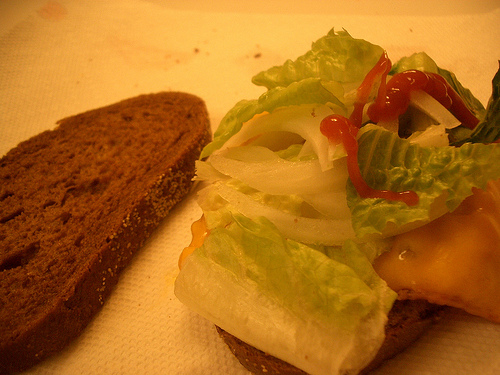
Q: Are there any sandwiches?
A: Yes, there is a sandwich.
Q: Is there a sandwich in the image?
A: Yes, there is a sandwich.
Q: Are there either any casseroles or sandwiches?
A: Yes, there is a sandwich.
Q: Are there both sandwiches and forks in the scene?
A: No, there is a sandwich but no forks.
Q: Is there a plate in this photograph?
A: No, there are no plates.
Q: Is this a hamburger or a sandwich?
A: This is a sandwich.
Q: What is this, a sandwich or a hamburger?
A: This is a sandwich.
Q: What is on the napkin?
A: The sandwich is on the napkin.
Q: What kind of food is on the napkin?
A: The food is a sandwich.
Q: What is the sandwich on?
A: The sandwich is on the napkin.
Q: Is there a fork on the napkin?
A: No, there is a sandwich on the napkin.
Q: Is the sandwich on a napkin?
A: Yes, the sandwich is on a napkin.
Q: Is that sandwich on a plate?
A: No, the sandwich is on a napkin.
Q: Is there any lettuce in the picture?
A: Yes, there is lettuce.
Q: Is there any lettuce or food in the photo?
A: Yes, there is lettuce.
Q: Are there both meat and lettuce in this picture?
A: No, there is lettuce but no meat.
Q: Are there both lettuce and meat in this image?
A: No, there is lettuce but no meat.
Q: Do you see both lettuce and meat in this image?
A: No, there is lettuce but no meat.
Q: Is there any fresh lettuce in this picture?
A: Yes, there is fresh lettuce.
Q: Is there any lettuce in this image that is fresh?
A: Yes, there is lettuce that is fresh.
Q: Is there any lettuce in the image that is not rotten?
A: Yes, there is fresh lettuce.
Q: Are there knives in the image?
A: No, there are no knives.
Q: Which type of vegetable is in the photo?
A: The vegetable is lettuce.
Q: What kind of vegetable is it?
A: The vegetable is lettuce.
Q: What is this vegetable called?
A: That is lettuce.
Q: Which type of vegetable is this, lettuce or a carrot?
A: That is lettuce.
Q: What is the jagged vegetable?
A: The vegetable is lettuce.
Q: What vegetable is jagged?
A: The vegetable is lettuce.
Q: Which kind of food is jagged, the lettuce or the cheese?
A: The lettuce is jagged.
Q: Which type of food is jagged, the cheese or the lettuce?
A: The lettuce is jagged.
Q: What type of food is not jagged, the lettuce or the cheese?
A: The cheese is not jagged.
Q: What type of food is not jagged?
A: The food is cheese.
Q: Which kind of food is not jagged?
A: The food is cheese.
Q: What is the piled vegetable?
A: The vegetable is lettuce.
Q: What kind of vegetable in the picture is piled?
A: The vegetable is lettuce.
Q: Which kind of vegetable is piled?
A: The vegetable is lettuce.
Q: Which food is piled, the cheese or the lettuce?
A: The lettuce is piled.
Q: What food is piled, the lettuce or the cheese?
A: The lettuce is piled.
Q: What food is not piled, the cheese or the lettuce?
A: The cheese is not piled.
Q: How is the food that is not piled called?
A: The food is cheese.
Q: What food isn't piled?
A: The food is cheese.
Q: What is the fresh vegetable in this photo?
A: The vegetable is lettuce.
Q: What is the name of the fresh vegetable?
A: The vegetable is lettuce.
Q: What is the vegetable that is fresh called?
A: The vegetable is lettuce.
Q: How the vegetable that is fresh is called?
A: The vegetable is lettuce.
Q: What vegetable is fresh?
A: The vegetable is lettuce.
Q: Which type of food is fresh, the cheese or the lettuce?
A: The lettuce is fresh.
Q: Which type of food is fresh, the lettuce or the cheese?
A: The lettuce is fresh.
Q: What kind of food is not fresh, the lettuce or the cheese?
A: The cheese is not fresh.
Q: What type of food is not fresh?
A: The food is cheese.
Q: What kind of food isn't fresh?
A: The food is cheese.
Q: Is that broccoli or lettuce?
A: That is lettuce.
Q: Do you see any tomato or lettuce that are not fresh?
A: No, there is lettuce but it is fresh.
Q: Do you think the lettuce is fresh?
A: Yes, the lettuce is fresh.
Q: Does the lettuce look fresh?
A: Yes, the lettuce is fresh.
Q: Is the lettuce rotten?
A: No, the lettuce is fresh.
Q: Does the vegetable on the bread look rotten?
A: No, the lettuce is fresh.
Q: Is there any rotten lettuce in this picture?
A: No, there is lettuce but it is fresh.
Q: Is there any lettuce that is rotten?
A: No, there is lettuce but it is fresh.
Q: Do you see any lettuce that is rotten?
A: No, there is lettuce but it is fresh.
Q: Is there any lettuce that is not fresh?
A: No, there is lettuce but it is fresh.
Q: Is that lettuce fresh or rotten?
A: The lettuce is fresh.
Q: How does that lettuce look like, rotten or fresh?
A: The lettuce is fresh.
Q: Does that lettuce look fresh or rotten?
A: The lettuce is fresh.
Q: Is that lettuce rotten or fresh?
A: The lettuce is fresh.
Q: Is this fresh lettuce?
A: Yes, this is fresh lettuce.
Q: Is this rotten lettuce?
A: No, this is fresh lettuce.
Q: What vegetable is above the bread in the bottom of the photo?
A: The vegetable is lettuce.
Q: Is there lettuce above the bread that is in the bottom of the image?
A: Yes, there is lettuce above the bread.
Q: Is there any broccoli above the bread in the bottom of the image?
A: No, there is lettuce above the bread.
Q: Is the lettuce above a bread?
A: Yes, the lettuce is above a bread.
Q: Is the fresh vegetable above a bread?
A: Yes, the lettuce is above a bread.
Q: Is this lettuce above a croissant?
A: No, the lettuce is above a bread.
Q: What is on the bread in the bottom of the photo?
A: The lettuce is on the bread.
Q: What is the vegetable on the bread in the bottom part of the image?
A: The vegetable is lettuce.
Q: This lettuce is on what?
A: The lettuce is on the bread.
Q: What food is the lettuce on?
A: The lettuce is on the bread.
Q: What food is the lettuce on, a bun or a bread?
A: The lettuce is on a bread.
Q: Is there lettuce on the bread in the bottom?
A: Yes, there is lettuce on the bread.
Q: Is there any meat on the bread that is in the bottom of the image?
A: No, there is lettuce on the bread.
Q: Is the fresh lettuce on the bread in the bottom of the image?
A: Yes, the lettuce is on the bread.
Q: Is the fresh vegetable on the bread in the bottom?
A: Yes, the lettuce is on the bread.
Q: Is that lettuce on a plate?
A: No, the lettuce is on the bread.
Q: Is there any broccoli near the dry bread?
A: No, there is lettuce near the bread.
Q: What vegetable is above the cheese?
A: The vegetable is lettuce.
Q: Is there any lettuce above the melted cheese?
A: Yes, there is lettuce above the cheese.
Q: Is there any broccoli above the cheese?
A: No, there is lettuce above the cheese.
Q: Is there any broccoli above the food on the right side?
A: No, there is lettuce above the cheese.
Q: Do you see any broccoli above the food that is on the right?
A: No, there is lettuce above the cheese.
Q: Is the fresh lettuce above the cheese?
A: Yes, the lettuce is above the cheese.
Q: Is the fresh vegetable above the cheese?
A: Yes, the lettuce is above the cheese.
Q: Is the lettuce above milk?
A: No, the lettuce is above the cheese.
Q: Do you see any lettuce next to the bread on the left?
A: Yes, there is lettuce next to the bread.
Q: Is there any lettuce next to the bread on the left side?
A: Yes, there is lettuce next to the bread.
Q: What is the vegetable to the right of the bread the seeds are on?
A: The vegetable is lettuce.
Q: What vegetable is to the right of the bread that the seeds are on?
A: The vegetable is lettuce.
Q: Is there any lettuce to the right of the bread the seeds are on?
A: Yes, there is lettuce to the right of the bread.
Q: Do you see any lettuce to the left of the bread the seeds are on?
A: No, the lettuce is to the right of the bread.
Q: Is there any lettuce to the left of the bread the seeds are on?
A: No, the lettuce is to the right of the bread.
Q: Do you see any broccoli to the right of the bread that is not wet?
A: No, there is lettuce to the right of the bread.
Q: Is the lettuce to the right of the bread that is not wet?
A: Yes, the lettuce is to the right of the bread.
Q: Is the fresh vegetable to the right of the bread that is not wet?
A: Yes, the lettuce is to the right of the bread.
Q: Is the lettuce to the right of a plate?
A: No, the lettuce is to the right of the bread.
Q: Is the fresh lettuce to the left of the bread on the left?
A: No, the lettuce is to the right of the bread.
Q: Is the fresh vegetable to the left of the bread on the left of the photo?
A: No, the lettuce is to the right of the bread.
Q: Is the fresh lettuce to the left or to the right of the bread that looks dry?
A: The lettuce is to the right of the bread.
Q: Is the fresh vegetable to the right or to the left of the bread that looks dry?
A: The lettuce is to the right of the bread.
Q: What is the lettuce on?
A: The lettuce is on the bread.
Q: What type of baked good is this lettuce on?
A: The lettuce is on the bread.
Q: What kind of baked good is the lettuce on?
A: The lettuce is on the bread.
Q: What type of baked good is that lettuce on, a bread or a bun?
A: The lettuce is on a bread.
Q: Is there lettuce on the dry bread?
A: Yes, there is lettuce on the bread.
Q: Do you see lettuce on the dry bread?
A: Yes, there is lettuce on the bread.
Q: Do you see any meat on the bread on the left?
A: No, there is lettuce on the bread.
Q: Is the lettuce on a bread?
A: Yes, the lettuce is on a bread.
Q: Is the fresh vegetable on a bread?
A: Yes, the lettuce is on a bread.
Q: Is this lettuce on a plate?
A: No, the lettuce is on a bread.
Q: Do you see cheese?
A: Yes, there is cheese.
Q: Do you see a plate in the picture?
A: No, there are no plates.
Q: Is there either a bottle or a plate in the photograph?
A: No, there are no plates or bottles.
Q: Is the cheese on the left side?
A: No, the cheese is on the right of the image.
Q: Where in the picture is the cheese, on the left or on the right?
A: The cheese is on the right of the image.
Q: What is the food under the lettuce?
A: The food is cheese.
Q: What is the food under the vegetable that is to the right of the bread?
A: The food is cheese.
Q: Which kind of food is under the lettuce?
A: The food is cheese.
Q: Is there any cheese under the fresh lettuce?
A: Yes, there is cheese under the lettuce.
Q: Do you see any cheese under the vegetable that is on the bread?
A: Yes, there is cheese under the lettuce.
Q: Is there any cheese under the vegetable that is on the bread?
A: Yes, there is cheese under the lettuce.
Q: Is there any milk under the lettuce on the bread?
A: No, there is cheese under the lettuce.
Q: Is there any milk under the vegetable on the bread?
A: No, there is cheese under the lettuce.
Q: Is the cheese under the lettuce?
A: Yes, the cheese is under the lettuce.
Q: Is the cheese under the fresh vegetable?
A: Yes, the cheese is under the lettuce.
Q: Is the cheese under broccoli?
A: No, the cheese is under the lettuce.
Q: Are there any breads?
A: Yes, there is a bread.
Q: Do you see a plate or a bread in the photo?
A: Yes, there is a bread.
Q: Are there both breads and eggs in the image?
A: No, there is a bread but no eggs.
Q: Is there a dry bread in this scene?
A: Yes, there is a dry bread.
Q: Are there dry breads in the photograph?
A: Yes, there is a dry bread.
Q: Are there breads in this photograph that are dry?
A: Yes, there is a bread that is dry.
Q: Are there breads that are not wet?
A: Yes, there is a dry bread.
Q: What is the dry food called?
A: The food is a bread.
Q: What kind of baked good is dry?
A: The baked good is a bread.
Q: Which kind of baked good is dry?
A: The baked good is a bread.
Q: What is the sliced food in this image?
A: The food is a bread.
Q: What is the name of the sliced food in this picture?
A: The food is a bread.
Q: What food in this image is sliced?
A: The food is a bread.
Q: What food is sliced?
A: The food is a bread.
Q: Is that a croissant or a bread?
A: That is a bread.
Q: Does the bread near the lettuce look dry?
A: Yes, the bread is dry.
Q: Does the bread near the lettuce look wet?
A: No, the bread is dry.